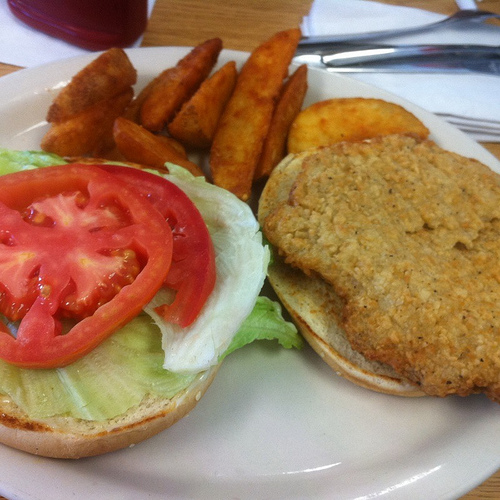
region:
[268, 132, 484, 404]
This is a pork fritter sandwich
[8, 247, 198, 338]
Slices of tomato on lettuce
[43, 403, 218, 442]
The bun is lightly toasted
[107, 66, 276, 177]
These are batter dipped french fries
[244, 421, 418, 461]
The food is on a white plate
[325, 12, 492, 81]
A fork and knife on a napkin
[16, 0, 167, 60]
A bottle of ketchup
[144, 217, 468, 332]
this is a nice lunch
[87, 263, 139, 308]
Seeds of the tomato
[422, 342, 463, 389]
The pork patty is battered and seasonedseasoned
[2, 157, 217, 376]
two red slices of tomato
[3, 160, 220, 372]
two slices of tomato on lettuce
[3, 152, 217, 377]
lettuce under slices of tomato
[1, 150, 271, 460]
lettuce and tomato on a grilled bun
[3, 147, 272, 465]
grilled bun topped with lettuce and tomato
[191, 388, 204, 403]
sesame seed on a bun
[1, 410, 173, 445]
toasted edge of a bun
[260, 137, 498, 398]
crunchy patty on a toasted bun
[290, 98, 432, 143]
potato wedge on a plate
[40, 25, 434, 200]
potato wedges on a plate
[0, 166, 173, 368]
large size of tomato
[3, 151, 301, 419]
lettuce under tomato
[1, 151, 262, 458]
bun with lettuce and tomato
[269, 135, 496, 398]
chicken patty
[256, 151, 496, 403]
bun with chicken patty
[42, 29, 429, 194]
fried potato wedges on side of plate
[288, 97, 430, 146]
lighter colored potato wedge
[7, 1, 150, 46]
bottom of ketchup bottle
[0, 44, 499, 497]
plate with sandwich and wedges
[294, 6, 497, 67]
silver utensils on paper napkins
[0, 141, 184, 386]
peice of food on a plate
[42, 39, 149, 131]
peice of food on a plate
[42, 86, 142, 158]
peice of food on a plate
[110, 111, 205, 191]
peice of food on a plate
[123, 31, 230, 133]
peice of food on a plate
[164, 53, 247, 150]
peice of food on a plate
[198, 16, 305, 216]
peice of food on a plate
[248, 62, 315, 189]
peice of food on a plate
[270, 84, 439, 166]
peice of food on a plate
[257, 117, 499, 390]
peice of food on a plate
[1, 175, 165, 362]
Whole slice of tomato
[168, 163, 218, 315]
Partial slice of tomato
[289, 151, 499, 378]
Breaded chicken patty on bread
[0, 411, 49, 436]
Browned edges of bun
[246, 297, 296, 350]
Green piece of lettuce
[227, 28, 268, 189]
Long golden brown potato wedge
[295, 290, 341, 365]
Toasted sandwich bun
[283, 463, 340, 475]
Reflection of light on white plate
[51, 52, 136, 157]
Pile of crispy brown potato wedges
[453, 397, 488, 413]
Dark shadow on white plate